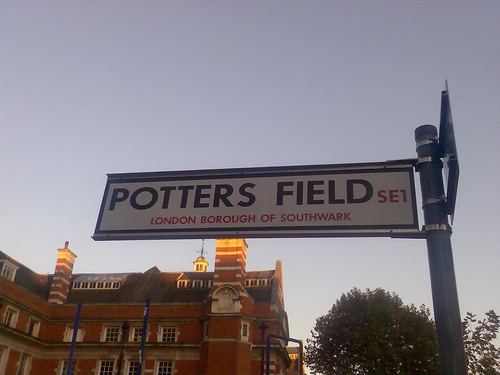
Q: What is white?
A: A sign.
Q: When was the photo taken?
A: During the day.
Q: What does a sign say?
A: "POTTERS FIELD".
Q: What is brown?
A: Building.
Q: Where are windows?
A: On a building.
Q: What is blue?
A: The sky.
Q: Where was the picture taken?
A: On a street.